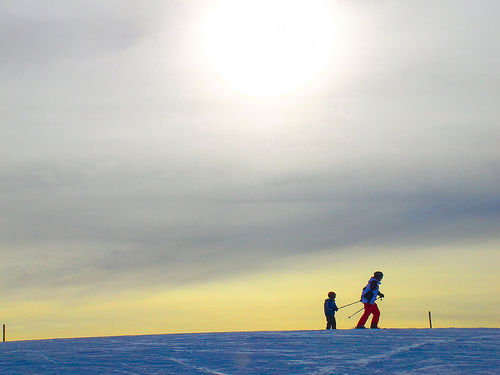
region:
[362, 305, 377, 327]
The red pants the person is wearing.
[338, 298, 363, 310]
The left ski pole.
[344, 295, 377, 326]
The right ski pole.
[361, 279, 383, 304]
The blue and black jacket the adult is wearing.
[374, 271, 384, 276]
The helmet on the adult.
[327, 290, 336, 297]
The helmet the child is wearing.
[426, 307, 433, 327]
The pole on the right.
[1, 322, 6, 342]
The pole on the left.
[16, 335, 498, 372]
The snow on the ground.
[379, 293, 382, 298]
The black glove on the person's hand.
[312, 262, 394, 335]
people skiing on snow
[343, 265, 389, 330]
a person skiing in the snow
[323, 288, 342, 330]
a little kid in the snow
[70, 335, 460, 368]
snow on the ground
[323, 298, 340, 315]
a little kid with a blue jacket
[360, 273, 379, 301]
a person wearing a blue jacket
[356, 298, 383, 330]
a person wearing red snow pants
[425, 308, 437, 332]
a pole in the snow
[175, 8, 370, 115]
sun shining through clouds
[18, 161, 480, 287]
clouds in the sky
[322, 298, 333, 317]
The blue coat the child is wearing.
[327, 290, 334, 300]
The black helmet the child is wearing.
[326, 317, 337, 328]
The pants the child is wearing.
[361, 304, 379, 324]
The red pants the adult is wearing.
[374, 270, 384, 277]
The helmet the adult is wearing.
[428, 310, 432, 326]
The pole on the right.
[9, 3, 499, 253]
The clouds in the sky.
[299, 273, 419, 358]
two people walking in the snow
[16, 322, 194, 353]
horizon line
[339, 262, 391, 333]
person walking with ski poles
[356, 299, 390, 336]
person wearing red ski pants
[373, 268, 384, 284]
person wearing a helmet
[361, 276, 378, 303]
person wearing a black and white ski jacket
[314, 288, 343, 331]
child on the snow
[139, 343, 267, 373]
snow covering the ground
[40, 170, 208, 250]
grey clouds in the sky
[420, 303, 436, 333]
pole sticking up